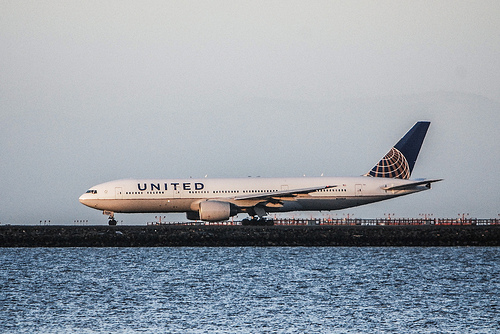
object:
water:
[0, 244, 499, 334]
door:
[116, 187, 123, 200]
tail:
[363, 118, 442, 196]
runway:
[0, 221, 500, 234]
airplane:
[76, 120, 444, 226]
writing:
[136, 182, 205, 192]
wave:
[218, 256, 310, 310]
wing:
[231, 184, 336, 201]